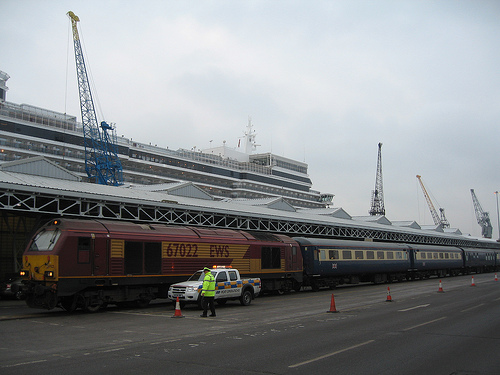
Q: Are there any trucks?
A: Yes, there is a truck.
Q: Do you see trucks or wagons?
A: Yes, there is a truck.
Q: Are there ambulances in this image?
A: No, there are no ambulances.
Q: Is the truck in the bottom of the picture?
A: Yes, the truck is in the bottom of the image.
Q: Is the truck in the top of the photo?
A: No, the truck is in the bottom of the image.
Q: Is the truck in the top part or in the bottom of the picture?
A: The truck is in the bottom of the image.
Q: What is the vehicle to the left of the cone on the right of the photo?
A: The vehicle is a truck.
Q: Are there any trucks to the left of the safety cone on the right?
A: Yes, there is a truck to the left of the safety cone.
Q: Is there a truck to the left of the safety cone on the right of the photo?
A: Yes, there is a truck to the left of the safety cone.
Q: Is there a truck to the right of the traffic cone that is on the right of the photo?
A: No, the truck is to the left of the cone.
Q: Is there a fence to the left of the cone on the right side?
A: No, there is a truck to the left of the traffic cone.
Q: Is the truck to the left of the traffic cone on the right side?
A: Yes, the truck is to the left of the cone.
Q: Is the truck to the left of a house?
A: No, the truck is to the left of the cone.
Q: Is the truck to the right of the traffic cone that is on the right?
A: No, the truck is to the left of the traffic cone.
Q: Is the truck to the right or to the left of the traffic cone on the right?
A: The truck is to the left of the traffic cone.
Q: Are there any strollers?
A: No, there are no strollers.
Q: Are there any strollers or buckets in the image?
A: No, there are no strollers or buckets.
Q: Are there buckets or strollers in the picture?
A: No, there are no strollers or buckets.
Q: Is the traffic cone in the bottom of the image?
A: Yes, the traffic cone is in the bottom of the image.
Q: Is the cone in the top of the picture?
A: No, the cone is in the bottom of the image.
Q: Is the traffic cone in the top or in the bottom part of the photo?
A: The traffic cone is in the bottom of the image.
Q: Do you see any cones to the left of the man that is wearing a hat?
A: Yes, there is a cone to the left of the man.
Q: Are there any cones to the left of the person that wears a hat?
A: Yes, there is a cone to the left of the man.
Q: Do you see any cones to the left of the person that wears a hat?
A: Yes, there is a cone to the left of the man.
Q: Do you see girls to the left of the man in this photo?
A: No, there is a cone to the left of the man.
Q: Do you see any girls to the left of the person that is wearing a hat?
A: No, there is a cone to the left of the man.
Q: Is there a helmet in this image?
A: No, there are no helmets.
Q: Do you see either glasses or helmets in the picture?
A: No, there are no helmets or glasses.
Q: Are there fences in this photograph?
A: No, there are no fences.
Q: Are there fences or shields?
A: No, there are no fences or shields.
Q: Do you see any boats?
A: Yes, there is a boat.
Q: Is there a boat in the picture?
A: Yes, there is a boat.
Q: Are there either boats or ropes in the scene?
A: Yes, there is a boat.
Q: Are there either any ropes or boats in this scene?
A: Yes, there is a boat.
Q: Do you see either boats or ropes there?
A: Yes, there is a boat.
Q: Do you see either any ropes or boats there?
A: Yes, there is a boat.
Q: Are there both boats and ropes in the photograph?
A: No, there is a boat but no ropes.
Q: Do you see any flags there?
A: No, there are no flags.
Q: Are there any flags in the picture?
A: No, there are no flags.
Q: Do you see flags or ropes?
A: No, there are no flags or ropes.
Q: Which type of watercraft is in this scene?
A: The watercraft is a boat.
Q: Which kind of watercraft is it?
A: The watercraft is a boat.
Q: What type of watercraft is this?
A: This is a boat.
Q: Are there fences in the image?
A: No, there are no fences.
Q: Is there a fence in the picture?
A: No, there are no fences.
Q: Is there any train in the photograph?
A: Yes, there is a train.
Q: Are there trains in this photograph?
A: Yes, there is a train.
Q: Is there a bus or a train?
A: Yes, there is a train.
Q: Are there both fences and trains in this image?
A: No, there is a train but no fences.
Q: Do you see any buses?
A: No, there are no buses.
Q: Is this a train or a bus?
A: This is a train.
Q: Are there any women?
A: No, there are no women.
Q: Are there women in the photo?
A: No, there are no women.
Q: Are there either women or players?
A: No, there are no women or players.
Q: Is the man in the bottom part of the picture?
A: Yes, the man is in the bottom of the image.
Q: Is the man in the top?
A: No, the man is in the bottom of the image.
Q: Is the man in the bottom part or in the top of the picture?
A: The man is in the bottom of the image.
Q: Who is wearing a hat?
A: The man is wearing a hat.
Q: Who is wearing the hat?
A: The man is wearing a hat.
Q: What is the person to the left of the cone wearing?
A: The man is wearing a hat.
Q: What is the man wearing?
A: The man is wearing a hat.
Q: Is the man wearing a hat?
A: Yes, the man is wearing a hat.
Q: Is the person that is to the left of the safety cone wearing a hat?
A: Yes, the man is wearing a hat.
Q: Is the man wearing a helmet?
A: No, the man is wearing a hat.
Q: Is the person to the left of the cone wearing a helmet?
A: No, the man is wearing a hat.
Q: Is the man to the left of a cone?
A: Yes, the man is to the left of a cone.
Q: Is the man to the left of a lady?
A: No, the man is to the left of a cone.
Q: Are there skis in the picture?
A: No, there are no skis.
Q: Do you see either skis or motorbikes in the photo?
A: No, there are no skis or motorbikes.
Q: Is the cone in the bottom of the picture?
A: Yes, the cone is in the bottom of the image.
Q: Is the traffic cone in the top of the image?
A: No, the traffic cone is in the bottom of the image.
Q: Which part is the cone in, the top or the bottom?
A: The cone is in the bottom of the image.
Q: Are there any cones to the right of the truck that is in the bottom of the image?
A: Yes, there is a cone to the right of the truck.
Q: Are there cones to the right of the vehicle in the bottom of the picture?
A: Yes, there is a cone to the right of the truck.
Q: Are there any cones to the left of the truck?
A: No, the cone is to the right of the truck.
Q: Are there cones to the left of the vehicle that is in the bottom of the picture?
A: No, the cone is to the right of the truck.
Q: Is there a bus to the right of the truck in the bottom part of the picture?
A: No, there is a cone to the right of the truck.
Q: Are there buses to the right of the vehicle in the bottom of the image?
A: No, there is a cone to the right of the truck.